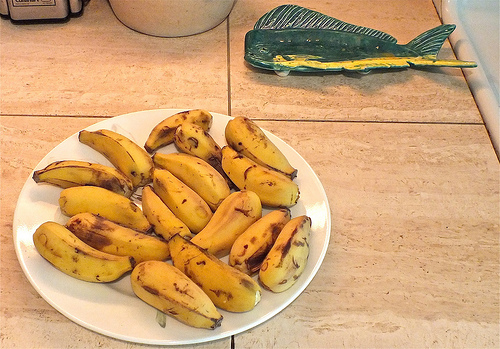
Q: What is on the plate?
A: Cut bananas.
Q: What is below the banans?
A: A plate.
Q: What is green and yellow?
A: A fish.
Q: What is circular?
A: The plate.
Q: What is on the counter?
A: Square tile.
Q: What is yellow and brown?
A: Bananas.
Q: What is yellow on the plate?
A: Bananas.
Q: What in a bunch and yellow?
A: Bananas.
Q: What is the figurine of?
A: A fish.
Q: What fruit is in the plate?
A: Bananas.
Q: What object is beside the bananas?
A: A fish.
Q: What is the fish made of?
A: Ceramic.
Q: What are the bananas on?
A: A plate.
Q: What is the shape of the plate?
A: Round.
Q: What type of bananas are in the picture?
A: Baby bananas.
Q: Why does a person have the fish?
A: Decoration.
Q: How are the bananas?
A: Bruised.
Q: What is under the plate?
A: Tiles.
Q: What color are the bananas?
A: Yellow.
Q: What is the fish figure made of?
A: Glass.